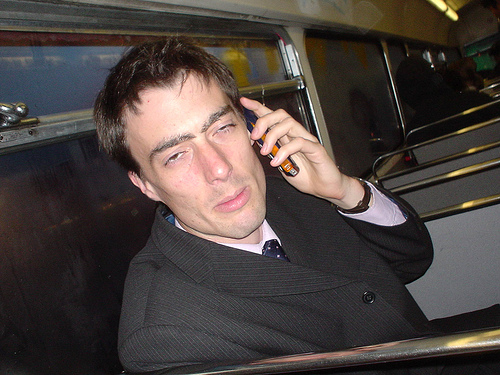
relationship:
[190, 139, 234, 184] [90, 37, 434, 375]
nose of man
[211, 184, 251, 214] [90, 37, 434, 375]
mouth of man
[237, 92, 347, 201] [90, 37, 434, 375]
hand of man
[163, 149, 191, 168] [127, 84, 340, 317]
eye of man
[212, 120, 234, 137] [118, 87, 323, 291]
eye of man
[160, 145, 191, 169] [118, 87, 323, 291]
eye of man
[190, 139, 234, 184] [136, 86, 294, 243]
nose of man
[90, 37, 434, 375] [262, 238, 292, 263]
man wearing tie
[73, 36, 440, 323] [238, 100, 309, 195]
man on phone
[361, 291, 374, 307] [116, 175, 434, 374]
button on suit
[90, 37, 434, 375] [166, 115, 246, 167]
man has eyes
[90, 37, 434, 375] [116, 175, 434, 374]
man wearing suit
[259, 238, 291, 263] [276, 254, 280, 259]
tie has dot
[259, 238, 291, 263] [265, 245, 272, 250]
tie has dot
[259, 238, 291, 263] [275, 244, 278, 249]
tie has dot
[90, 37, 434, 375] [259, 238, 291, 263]
man has tie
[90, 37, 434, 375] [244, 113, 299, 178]
man holding cell phone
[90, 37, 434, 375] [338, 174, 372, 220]
man wearing wristwatch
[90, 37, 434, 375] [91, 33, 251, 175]
man has hair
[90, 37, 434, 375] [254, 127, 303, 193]
man on phone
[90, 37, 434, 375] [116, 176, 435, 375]
man wearing pinstripe suit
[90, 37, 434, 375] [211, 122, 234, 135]
man has eye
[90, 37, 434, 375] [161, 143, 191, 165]
man has eye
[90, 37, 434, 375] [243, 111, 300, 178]
man on cell phone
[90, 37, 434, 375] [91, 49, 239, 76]
man has hair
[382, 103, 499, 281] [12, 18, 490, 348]
seats on bus